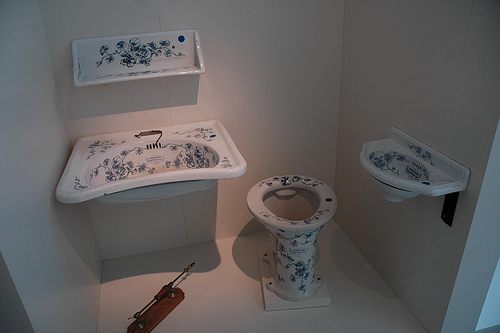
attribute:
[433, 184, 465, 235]
bracket — black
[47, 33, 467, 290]
bathroom — small 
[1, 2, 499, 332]
bathroom — decorated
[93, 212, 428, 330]
floor — white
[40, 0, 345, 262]
wall — white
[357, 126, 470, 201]
sink — blue, white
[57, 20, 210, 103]
shelf — porcelain, decorative, blue, white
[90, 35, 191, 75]
flowers — blue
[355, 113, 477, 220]
sink — porcelain, decorative, ornate, small, white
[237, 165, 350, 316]
toilet — porcelain, blue, white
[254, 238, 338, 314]
base — white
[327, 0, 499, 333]
wall — white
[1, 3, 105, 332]
wall — white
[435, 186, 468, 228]
bracket — black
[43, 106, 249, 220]
sink — porcelain, decorative, ornate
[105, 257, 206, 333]
object — wooden, red